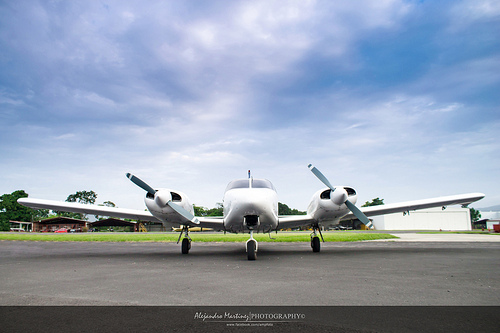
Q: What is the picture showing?
A: It is showing an airport.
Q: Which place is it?
A: It is an airport.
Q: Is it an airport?
A: Yes, it is an airport.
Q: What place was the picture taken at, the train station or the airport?
A: It was taken at the airport.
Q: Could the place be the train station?
A: No, it is the airport.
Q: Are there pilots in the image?
A: No, there are no pilots.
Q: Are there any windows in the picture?
A: Yes, there are windows.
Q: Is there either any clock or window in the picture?
A: Yes, there are windows.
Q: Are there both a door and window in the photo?
A: No, there are windows but no doors.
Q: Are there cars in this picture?
A: No, there are no cars.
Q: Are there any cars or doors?
A: No, there are no cars or doors.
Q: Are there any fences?
A: No, there are no fences.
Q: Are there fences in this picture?
A: No, there are no fences.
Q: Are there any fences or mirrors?
A: No, there are no fences or mirrors.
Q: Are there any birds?
A: No, there are no birds.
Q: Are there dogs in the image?
A: No, there are no dogs.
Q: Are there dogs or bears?
A: No, there are no dogs or bears.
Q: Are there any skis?
A: No, there are no skis.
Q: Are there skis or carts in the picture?
A: No, there are no skis or carts.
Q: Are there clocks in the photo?
A: No, there are no clocks.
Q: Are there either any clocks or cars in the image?
A: No, there are no clocks or cars.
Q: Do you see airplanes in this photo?
A: Yes, there is an airplane.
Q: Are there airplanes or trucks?
A: Yes, there is an airplane.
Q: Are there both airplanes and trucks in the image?
A: No, there is an airplane but no trucks.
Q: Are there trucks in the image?
A: No, there are no trucks.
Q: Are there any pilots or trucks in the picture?
A: No, there are no trucks or pilots.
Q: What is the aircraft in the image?
A: The aircraft is an airplane.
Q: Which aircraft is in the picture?
A: The aircraft is an airplane.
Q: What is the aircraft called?
A: The aircraft is an airplane.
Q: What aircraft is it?
A: The aircraft is an airplane.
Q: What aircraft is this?
A: This is an airplane.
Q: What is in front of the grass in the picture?
A: The plane is in front of the grass.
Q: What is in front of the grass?
A: The plane is in front of the grass.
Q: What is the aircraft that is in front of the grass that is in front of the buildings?
A: The aircraft is an airplane.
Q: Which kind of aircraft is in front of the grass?
A: The aircraft is an airplane.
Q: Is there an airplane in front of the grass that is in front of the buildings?
A: Yes, there is an airplane in front of the grass.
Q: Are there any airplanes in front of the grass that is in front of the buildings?
A: Yes, there is an airplane in front of the grass.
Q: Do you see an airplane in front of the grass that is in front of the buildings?
A: Yes, there is an airplane in front of the grass.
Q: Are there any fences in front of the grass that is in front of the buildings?
A: No, there is an airplane in front of the grass.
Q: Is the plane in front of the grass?
A: Yes, the plane is in front of the grass.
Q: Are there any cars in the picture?
A: No, there are no cars.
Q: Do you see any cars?
A: No, there are no cars.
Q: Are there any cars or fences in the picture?
A: No, there are no cars or fences.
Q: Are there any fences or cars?
A: No, there are no cars or fences.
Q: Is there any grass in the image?
A: Yes, there is grass.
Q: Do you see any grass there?
A: Yes, there is grass.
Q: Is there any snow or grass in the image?
A: Yes, there is grass.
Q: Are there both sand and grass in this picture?
A: No, there is grass but no sand.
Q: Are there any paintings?
A: No, there are no paintings.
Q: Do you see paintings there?
A: No, there are no paintings.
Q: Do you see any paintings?
A: No, there are no paintings.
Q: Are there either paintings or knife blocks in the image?
A: No, there are no paintings or knife blocks.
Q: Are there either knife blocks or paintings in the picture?
A: No, there are no paintings or knife blocks.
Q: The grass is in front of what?
A: The grass is in front of the buildings.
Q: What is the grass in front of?
A: The grass is in front of the buildings.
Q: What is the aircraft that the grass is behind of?
A: The aircraft is an airplane.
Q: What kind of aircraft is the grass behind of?
A: The grass is behind the plane.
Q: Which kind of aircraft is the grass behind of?
A: The grass is behind the plane.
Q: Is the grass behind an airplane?
A: Yes, the grass is behind an airplane.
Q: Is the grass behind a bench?
A: No, the grass is behind an airplane.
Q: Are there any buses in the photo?
A: No, there are no buses.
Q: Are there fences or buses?
A: No, there are no buses or fences.